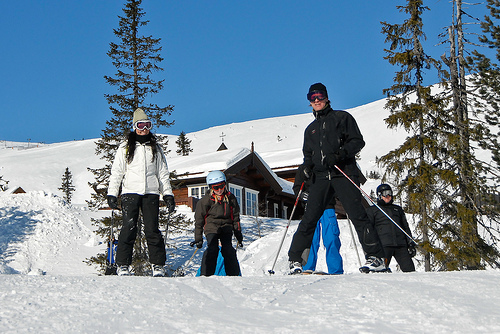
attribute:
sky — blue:
[185, 18, 332, 82]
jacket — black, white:
[118, 147, 170, 192]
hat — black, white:
[310, 88, 323, 93]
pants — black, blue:
[302, 180, 378, 262]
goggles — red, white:
[132, 118, 154, 131]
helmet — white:
[134, 111, 145, 122]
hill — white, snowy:
[21, 147, 95, 217]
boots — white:
[115, 257, 177, 278]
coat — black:
[302, 118, 356, 189]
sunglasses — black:
[310, 93, 328, 106]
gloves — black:
[323, 159, 344, 177]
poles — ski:
[277, 181, 307, 270]